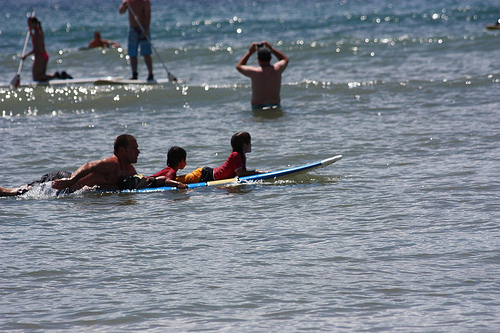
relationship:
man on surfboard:
[46, 128, 131, 186] [7, 179, 343, 201]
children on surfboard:
[156, 133, 254, 173] [7, 179, 343, 201]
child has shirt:
[171, 117, 269, 191] [208, 152, 261, 187]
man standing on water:
[193, 20, 306, 109] [0, 1, 497, 329]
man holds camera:
[232, 39, 290, 112] [253, 40, 270, 51]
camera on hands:
[253, 40, 270, 51] [247, 40, 272, 52]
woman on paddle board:
[14, 12, 51, 89] [24, 63, 164, 104]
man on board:
[113, 0, 158, 82] [94, 73, 182, 86]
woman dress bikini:
[22, 8, 76, 83] [29, 28, 52, 63]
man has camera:
[239, 40, 288, 116] [253, 40, 270, 51]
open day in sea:
[3, 2, 498, 330] [250, 94, 444, 201]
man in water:
[46, 128, 131, 186] [0, 1, 497, 329]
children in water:
[149, 133, 297, 173] [0, 1, 497, 329]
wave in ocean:
[0, 75, 499, 115] [0, 1, 499, 331]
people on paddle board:
[22, 3, 281, 178] [24, 63, 164, 104]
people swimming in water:
[96, 121, 226, 161] [184, 200, 394, 297]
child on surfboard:
[171, 117, 269, 191] [7, 179, 343, 201]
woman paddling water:
[14, 12, 51, 89] [0, 1, 497, 329]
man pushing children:
[4, 132, 146, 201] [149, 133, 297, 173]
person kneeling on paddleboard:
[13, 9, 75, 85] [5, 67, 190, 93]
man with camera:
[239, 40, 288, 116] [246, 40, 267, 49]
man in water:
[239, 40, 288, 116] [252, 207, 421, 309]